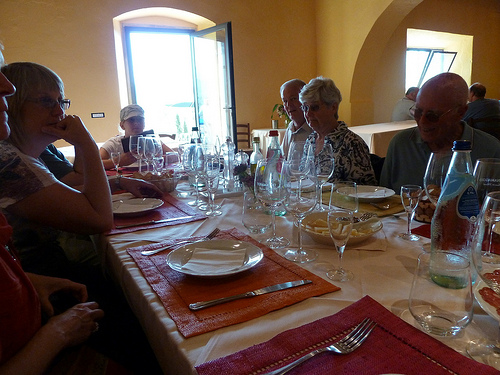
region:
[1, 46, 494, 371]
people sitting at a table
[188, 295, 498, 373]
a red place mat on a table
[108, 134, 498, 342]
various glasses of different sizes on a table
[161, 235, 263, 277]
a white plate with a white napkin in it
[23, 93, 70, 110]
woman wearing glasses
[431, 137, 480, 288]
an empty bottle of mineral water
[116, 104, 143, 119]
young man wearing a cap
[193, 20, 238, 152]
an opened window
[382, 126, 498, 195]
man wearing a blue shirt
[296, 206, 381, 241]
a bowl with pasta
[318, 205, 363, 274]
empty clear wine glass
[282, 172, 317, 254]
empty clear wine glass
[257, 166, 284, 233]
empty clear wine glass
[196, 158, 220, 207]
empty clear wine glass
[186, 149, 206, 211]
empty clear wine glass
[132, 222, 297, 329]
red place matt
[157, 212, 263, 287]
napkin on a white plate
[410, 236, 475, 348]
empty clear glass on table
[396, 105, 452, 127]
man wearing eye glasses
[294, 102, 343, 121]
woman wearing eye glasses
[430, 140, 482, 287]
Big empty glass bottle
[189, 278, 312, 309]
A metal utencil on a table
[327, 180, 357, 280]
A glass for wine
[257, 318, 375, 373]
A fork on a cloth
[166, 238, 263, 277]
A white plate with a napkin on it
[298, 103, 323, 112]
Sunglasses worn by a lady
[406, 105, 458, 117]
Eyeglasses worn by a man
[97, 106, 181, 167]
A lady sitting at a table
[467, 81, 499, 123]
Man sitting wearing a blue shirt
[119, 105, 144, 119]
A hat worn by a lady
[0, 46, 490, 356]
several people sharing a meal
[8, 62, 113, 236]
this woman is pensive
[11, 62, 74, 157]
the head of the pensive woman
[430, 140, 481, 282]
an empty bottle of water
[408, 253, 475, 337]
an empty glass of water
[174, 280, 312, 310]
a silver knife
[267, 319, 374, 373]
a silver folk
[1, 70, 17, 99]
the nose of someone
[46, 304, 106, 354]
one hand of someone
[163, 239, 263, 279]
a white napkinin the plate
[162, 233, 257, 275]
plate on top of red napkin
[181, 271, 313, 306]
knife on top of red napkin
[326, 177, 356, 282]
glass on top of table cloth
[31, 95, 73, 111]
glasses on women's face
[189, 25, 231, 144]
door in the room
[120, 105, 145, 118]
hat on boys head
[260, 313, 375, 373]
fork on red napkin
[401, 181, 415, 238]
short glass on table cloth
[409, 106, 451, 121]
glasses on man's face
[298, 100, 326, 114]
sunglasses on woman's face